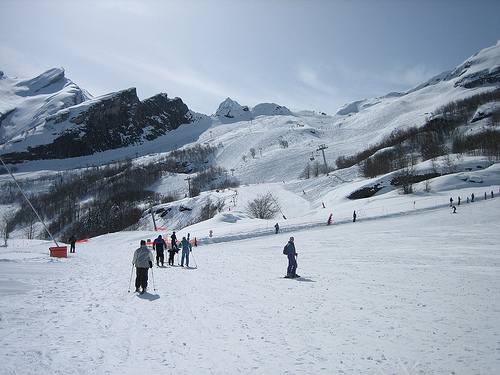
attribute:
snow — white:
[225, 297, 498, 362]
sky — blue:
[113, 17, 379, 73]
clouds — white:
[85, 5, 226, 89]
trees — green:
[29, 177, 142, 218]